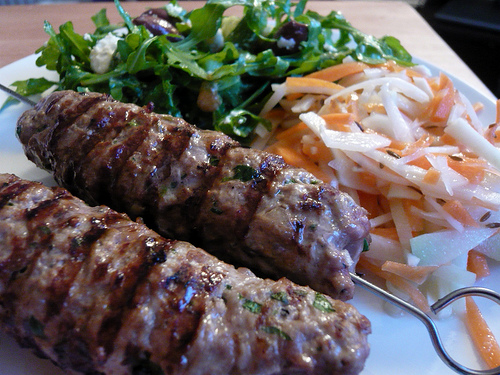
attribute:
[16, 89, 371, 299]
meat — grilled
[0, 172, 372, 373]
meat — grilled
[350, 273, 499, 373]
skewer — metal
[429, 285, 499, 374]
handle — round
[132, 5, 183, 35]
olive — marinated, greek , black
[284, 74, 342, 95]
carrot — shredded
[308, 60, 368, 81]
carrot — shredded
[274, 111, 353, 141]
carrot — shredded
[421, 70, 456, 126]
carrot — shredded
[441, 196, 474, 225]
carrot — shredded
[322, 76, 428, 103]
cabbage — shredded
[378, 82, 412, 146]
cabbage — shredded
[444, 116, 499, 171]
cabbage — shredded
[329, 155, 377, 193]
cabbage — shredded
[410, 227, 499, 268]
cabbage — shredded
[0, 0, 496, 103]
table — light colored, wood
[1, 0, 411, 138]
salad — green, tossed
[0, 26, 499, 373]
plate — white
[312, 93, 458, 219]
strips — carrot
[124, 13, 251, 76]
strips — lettuce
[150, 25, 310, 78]
strips — lettuce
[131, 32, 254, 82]
strips — lettuce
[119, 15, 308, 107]
strips — lettuce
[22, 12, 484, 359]
plate — white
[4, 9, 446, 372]
plate — round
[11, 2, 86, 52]
table — wooden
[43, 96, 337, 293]
lamb — grilled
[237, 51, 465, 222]
salad — sliced, daikon, carrot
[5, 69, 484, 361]
skewers — lamb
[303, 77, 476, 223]
carrots — cut, thin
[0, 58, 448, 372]
skewer — metal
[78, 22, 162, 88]
cheese — feta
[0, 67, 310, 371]
meat — pieces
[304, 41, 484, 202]
vegetables — some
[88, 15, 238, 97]
these — green, leafy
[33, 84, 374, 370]
meat — pieces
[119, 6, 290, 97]
leaves — green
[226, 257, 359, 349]
specks — green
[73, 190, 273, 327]
mark — char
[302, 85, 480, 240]
cheese — shredded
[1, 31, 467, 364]
plate — white